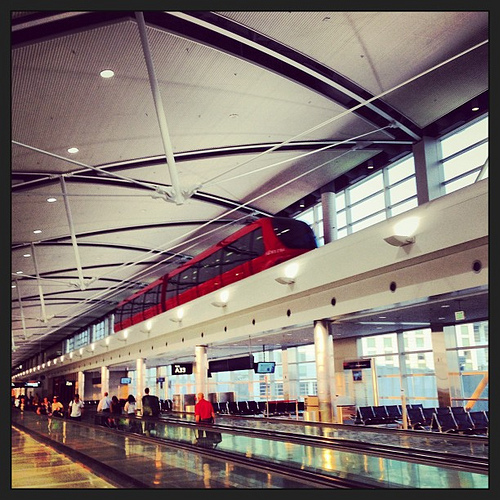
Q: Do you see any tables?
A: No, there are no tables.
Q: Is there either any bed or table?
A: No, there are no tables or beds.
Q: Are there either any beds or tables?
A: No, there are no tables or beds.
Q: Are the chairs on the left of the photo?
A: No, the chairs are on the right of the image.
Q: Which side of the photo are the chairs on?
A: The chairs are on the right of the image.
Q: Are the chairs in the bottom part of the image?
A: Yes, the chairs are in the bottom of the image.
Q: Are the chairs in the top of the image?
A: No, the chairs are in the bottom of the image.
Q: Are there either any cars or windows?
A: Yes, there is a window.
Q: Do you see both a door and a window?
A: No, there is a window but no doors.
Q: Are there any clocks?
A: No, there are no clocks.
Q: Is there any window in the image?
A: Yes, there are windows.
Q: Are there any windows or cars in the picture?
A: Yes, there are windows.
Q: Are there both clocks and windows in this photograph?
A: No, there are windows but no clocks.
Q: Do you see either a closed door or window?
A: Yes, there are closed windows.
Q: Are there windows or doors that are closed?
A: Yes, the windows are closed.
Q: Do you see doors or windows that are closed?
A: Yes, the windows are closed.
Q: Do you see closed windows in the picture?
A: Yes, there are closed windows.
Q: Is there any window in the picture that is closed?
A: Yes, there are windows that are closed.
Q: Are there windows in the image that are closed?
A: Yes, there are windows that are closed.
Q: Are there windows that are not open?
A: Yes, there are closed windows.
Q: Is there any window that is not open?
A: Yes, there are closed windows.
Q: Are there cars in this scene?
A: No, there are no cars.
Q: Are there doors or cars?
A: No, there are no cars or doors.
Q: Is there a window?
A: Yes, there are windows.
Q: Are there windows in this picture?
A: Yes, there are windows.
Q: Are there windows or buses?
A: Yes, there are windows.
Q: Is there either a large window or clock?
A: Yes, there are large windows.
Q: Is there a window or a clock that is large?
A: Yes, the windows are large.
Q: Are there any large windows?
A: Yes, there are large windows.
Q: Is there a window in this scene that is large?
A: Yes, there are windows that are large.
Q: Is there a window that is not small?
A: Yes, there are large windows.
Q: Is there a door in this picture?
A: No, there are no doors.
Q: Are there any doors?
A: No, there are no doors.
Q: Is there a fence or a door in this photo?
A: No, there are no doors or fences.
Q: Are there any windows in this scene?
A: Yes, there is a window.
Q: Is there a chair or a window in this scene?
A: Yes, there is a window.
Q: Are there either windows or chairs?
A: Yes, there is a window.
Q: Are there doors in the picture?
A: No, there are no doors.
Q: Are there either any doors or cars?
A: No, there are no doors or cars.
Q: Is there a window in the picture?
A: Yes, there is a window.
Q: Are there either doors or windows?
A: Yes, there is a window.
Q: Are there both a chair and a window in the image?
A: Yes, there are both a window and a chair.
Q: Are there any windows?
A: Yes, there is a window.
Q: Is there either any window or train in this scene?
A: Yes, there is a window.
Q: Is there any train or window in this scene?
A: Yes, there is a window.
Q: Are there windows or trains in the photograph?
A: Yes, there is a window.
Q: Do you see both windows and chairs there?
A: Yes, there are both a window and a chair.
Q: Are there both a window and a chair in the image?
A: Yes, there are both a window and a chair.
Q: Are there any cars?
A: No, there are no cars.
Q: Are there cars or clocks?
A: No, there are no cars or clocks.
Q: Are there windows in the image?
A: Yes, there is a window.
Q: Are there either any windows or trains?
A: Yes, there is a window.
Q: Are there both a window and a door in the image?
A: No, there is a window but no doors.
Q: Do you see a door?
A: No, there are no doors.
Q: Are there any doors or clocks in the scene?
A: No, there are no doors or clocks.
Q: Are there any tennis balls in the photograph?
A: No, there are no tennis balls.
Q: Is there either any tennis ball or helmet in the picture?
A: No, there are no tennis balls or helmets.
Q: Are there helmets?
A: No, there are no helmets.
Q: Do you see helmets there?
A: No, there are no helmets.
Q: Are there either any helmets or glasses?
A: No, there are no helmets or glasses.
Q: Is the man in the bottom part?
A: Yes, the man is in the bottom of the image.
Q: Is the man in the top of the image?
A: No, the man is in the bottom of the image.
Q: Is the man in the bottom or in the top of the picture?
A: The man is in the bottom of the image.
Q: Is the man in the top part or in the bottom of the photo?
A: The man is in the bottom of the image.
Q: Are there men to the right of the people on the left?
A: Yes, there is a man to the right of the people.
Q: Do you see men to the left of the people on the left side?
A: No, the man is to the right of the people.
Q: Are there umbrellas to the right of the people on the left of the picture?
A: No, there is a man to the right of the people.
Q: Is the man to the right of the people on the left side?
A: Yes, the man is to the right of the people.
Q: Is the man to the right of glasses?
A: No, the man is to the right of the people.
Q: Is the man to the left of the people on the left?
A: No, the man is to the right of the people.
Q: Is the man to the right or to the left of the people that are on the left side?
A: The man is to the right of the people.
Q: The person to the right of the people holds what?
A: The man holds the bag.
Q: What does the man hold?
A: The man holds the bag.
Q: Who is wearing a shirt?
A: The man is wearing a shirt.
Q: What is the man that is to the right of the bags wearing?
A: The man is wearing a shirt.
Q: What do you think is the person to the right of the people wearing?
A: The man is wearing a shirt.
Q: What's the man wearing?
A: The man is wearing a shirt.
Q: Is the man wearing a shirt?
A: Yes, the man is wearing a shirt.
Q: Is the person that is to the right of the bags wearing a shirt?
A: Yes, the man is wearing a shirt.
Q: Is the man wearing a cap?
A: No, the man is wearing a shirt.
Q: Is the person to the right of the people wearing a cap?
A: No, the man is wearing a shirt.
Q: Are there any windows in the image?
A: Yes, there are windows.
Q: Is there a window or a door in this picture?
A: Yes, there are windows.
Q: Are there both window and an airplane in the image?
A: No, there are windows but no airplanes.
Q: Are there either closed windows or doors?
A: Yes, there are closed windows.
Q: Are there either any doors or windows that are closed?
A: Yes, the windows are closed.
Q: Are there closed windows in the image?
A: Yes, there are closed windows.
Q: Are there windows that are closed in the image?
A: Yes, there are closed windows.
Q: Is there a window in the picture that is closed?
A: Yes, there are windows that are closed.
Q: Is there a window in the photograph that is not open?
A: Yes, there are closed windows.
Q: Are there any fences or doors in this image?
A: No, there are no doors or fences.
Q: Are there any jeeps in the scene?
A: No, there are no jeeps.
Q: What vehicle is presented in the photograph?
A: The vehicle is a carriage.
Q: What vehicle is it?
A: The vehicle is a carriage.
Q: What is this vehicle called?
A: That is a carriage.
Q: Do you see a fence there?
A: No, there are no fences.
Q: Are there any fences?
A: No, there are no fences.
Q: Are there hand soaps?
A: No, there are no hand soaps.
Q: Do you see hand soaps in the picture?
A: No, there are no hand soaps.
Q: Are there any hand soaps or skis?
A: No, there are no hand soaps or skis.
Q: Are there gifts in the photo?
A: No, there are no gifts.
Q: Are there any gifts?
A: No, there are no gifts.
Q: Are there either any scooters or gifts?
A: No, there are no gifts or scooters.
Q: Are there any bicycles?
A: No, there are no bicycles.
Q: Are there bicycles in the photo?
A: No, there are no bicycles.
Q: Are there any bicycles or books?
A: No, there are no bicycles or books.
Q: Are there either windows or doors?
A: Yes, there are windows.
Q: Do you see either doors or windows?
A: Yes, there are windows.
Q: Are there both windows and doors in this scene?
A: No, there are windows but no doors.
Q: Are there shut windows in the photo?
A: Yes, there are shut windows.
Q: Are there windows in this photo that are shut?
A: Yes, there are shut windows.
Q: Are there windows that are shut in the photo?
A: Yes, there are shut windows.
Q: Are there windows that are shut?
A: Yes, there are windows that are shut.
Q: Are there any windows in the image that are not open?
A: Yes, there are shut windows.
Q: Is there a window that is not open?
A: Yes, there are shut windows.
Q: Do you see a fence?
A: No, there are no fences.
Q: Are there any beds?
A: No, there are no beds.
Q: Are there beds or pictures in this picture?
A: No, there are no beds or pictures.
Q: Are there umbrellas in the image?
A: No, there are no umbrellas.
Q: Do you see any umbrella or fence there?
A: No, there are no umbrellas or fences.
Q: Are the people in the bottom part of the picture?
A: Yes, the people are in the bottom of the image.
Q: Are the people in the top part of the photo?
A: No, the people are in the bottom of the image.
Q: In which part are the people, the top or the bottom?
A: The people are in the bottom of the image.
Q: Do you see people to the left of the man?
A: Yes, there are people to the left of the man.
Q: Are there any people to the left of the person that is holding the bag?
A: Yes, there are people to the left of the man.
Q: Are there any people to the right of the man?
A: No, the people are to the left of the man.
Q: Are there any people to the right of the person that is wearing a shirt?
A: No, the people are to the left of the man.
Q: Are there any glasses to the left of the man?
A: No, there are people to the left of the man.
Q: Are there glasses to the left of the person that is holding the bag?
A: No, there are people to the left of the man.